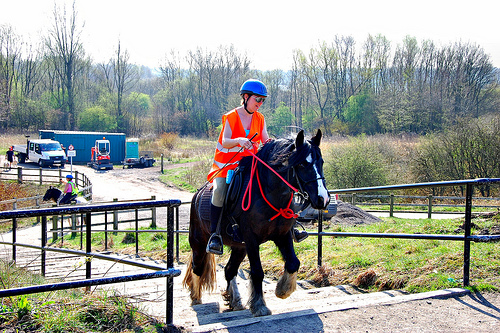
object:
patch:
[305, 152, 330, 207]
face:
[293, 142, 332, 211]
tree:
[450, 42, 500, 119]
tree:
[105, 39, 143, 133]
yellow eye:
[297, 163, 304, 167]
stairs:
[146, 282, 360, 322]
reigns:
[241, 138, 301, 212]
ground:
[325, 140, 500, 211]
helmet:
[239, 78, 268, 97]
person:
[208, 78, 308, 251]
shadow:
[189, 300, 326, 333]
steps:
[183, 286, 468, 332]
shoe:
[208, 231, 223, 251]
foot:
[208, 234, 221, 251]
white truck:
[13, 138, 68, 169]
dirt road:
[108, 159, 209, 194]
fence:
[0, 200, 184, 326]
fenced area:
[46, 210, 500, 293]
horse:
[181, 128, 332, 317]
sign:
[69, 145, 75, 151]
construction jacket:
[206, 106, 265, 183]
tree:
[36, 0, 93, 131]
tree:
[368, 34, 391, 93]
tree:
[282, 49, 314, 134]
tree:
[428, 48, 453, 102]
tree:
[397, 34, 422, 94]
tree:
[331, 32, 361, 117]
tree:
[287, 51, 308, 136]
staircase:
[171, 286, 417, 327]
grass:
[50, 211, 500, 294]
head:
[289, 128, 332, 210]